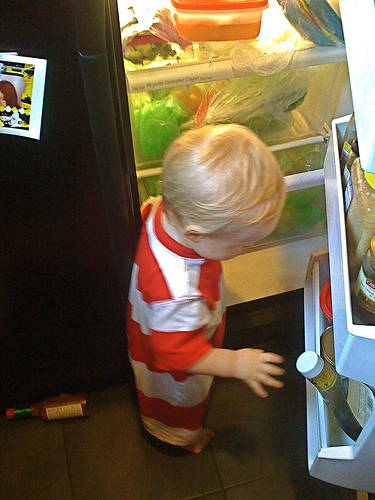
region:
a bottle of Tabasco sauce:
[3, 382, 106, 440]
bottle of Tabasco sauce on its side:
[1, 387, 95, 435]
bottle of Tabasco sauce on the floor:
[2, 381, 103, 441]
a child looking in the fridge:
[113, 112, 372, 494]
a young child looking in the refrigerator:
[115, 100, 372, 498]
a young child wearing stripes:
[108, 124, 289, 462]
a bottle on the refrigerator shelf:
[291, 345, 374, 461]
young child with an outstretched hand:
[89, 99, 300, 482]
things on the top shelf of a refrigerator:
[123, 1, 335, 81]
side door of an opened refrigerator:
[289, 103, 374, 497]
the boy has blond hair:
[162, 129, 290, 250]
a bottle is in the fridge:
[297, 348, 374, 441]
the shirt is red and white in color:
[132, 205, 222, 453]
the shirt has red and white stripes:
[134, 196, 216, 447]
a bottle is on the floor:
[8, 398, 86, 422]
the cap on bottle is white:
[295, 350, 322, 377]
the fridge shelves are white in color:
[299, 114, 374, 478]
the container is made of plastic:
[169, 2, 270, 39]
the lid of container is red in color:
[171, 0, 269, 11]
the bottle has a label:
[341, 375, 374, 435]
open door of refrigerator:
[2, 2, 372, 492]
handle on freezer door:
[74, 0, 151, 286]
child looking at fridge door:
[124, 122, 374, 453]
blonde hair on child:
[162, 123, 287, 236]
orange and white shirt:
[127, 195, 226, 445]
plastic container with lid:
[171, 1, 266, 41]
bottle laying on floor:
[5, 392, 90, 422]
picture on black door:
[1, 51, 47, 141]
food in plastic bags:
[140, 71, 311, 146]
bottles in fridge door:
[305, 115, 373, 487]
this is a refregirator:
[101, 14, 349, 131]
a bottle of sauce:
[6, 393, 84, 426]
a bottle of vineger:
[298, 358, 366, 424]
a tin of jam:
[352, 245, 372, 328]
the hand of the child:
[214, 347, 285, 391]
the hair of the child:
[205, 151, 271, 184]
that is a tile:
[56, 382, 210, 495]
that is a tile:
[7, 419, 63, 497]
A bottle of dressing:
[295, 350, 374, 443]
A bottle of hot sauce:
[6, 392, 89, 422]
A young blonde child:
[126, 122, 284, 453]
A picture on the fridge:
[0, 52, 48, 138]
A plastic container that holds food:
[169, 1, 268, 40]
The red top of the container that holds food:
[171, 0, 267, 10]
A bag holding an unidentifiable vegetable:
[191, 67, 307, 127]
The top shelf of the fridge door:
[323, 111, 373, 385]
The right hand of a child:
[236, 347, 285, 396]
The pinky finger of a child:
[250, 380, 267, 398]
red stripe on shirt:
[134, 231, 175, 302]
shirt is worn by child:
[126, 196, 225, 449]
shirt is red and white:
[126, 197, 225, 448]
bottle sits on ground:
[5, 390, 93, 420]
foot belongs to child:
[150, 419, 214, 453]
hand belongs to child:
[235, 343, 286, 398]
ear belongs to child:
[185, 225, 203, 243]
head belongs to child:
[158, 122, 286, 263]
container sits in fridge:
[169, 0, 270, 41]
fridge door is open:
[300, 0, 373, 495]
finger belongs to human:
[259, 348, 284, 365]